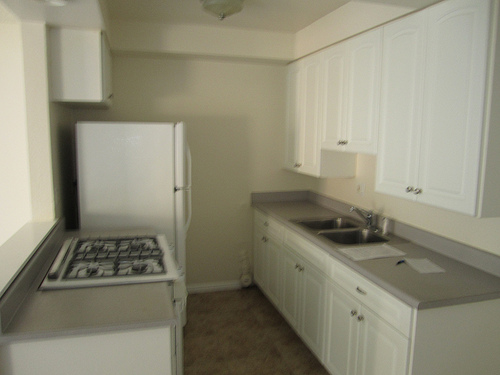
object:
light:
[199, 0, 239, 21]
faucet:
[349, 205, 372, 227]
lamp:
[203, 0, 239, 22]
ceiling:
[103, 2, 383, 62]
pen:
[396, 259, 406, 266]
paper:
[337, 243, 408, 262]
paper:
[402, 258, 447, 275]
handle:
[186, 144, 193, 232]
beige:
[109, 52, 294, 285]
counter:
[247, 202, 500, 375]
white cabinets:
[48, 22, 116, 112]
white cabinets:
[0, 275, 184, 375]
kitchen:
[8, 3, 476, 359]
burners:
[39, 232, 179, 290]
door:
[176, 122, 183, 189]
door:
[174, 190, 186, 327]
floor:
[208, 303, 300, 371]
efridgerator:
[74, 117, 191, 331]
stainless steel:
[289, 214, 406, 247]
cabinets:
[281, 0, 500, 219]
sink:
[296, 209, 388, 250]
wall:
[69, 53, 287, 292]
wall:
[280, 116, 498, 302]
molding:
[184, 280, 246, 295]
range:
[60, 234, 164, 278]